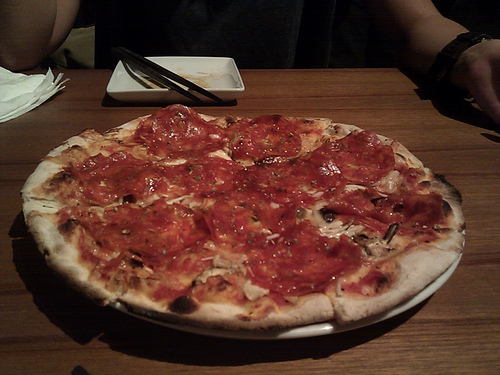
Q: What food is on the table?
A: Pizza.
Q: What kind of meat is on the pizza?
A: Pepperoni.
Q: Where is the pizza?
A: Sitting on the table.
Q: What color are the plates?
A: White.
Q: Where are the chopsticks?
A: Sitting on the plate in the background.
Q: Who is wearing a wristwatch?
A: The person across from the camera.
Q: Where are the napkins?
A: In the corner of the table.